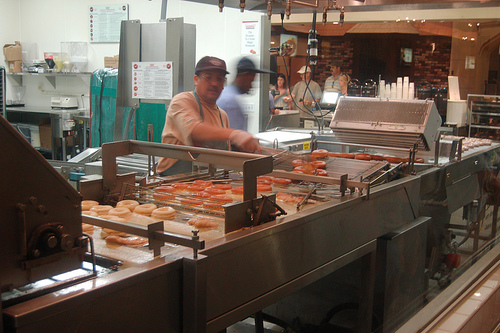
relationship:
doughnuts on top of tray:
[310, 146, 325, 157] [271, 147, 382, 186]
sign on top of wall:
[87, 7, 127, 43] [4, 2, 256, 128]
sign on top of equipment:
[132, 59, 173, 99] [122, 19, 196, 102]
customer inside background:
[270, 61, 351, 112] [272, 19, 500, 116]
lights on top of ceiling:
[349, 2, 371, 7] [284, 0, 499, 24]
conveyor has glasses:
[156, 56, 262, 177] [200, 75, 228, 88]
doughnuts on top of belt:
[310, 146, 325, 157] [271, 147, 382, 186]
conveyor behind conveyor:
[156, 56, 262, 177] [15, 92, 499, 308]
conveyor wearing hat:
[156, 56, 262, 177] [196, 56, 229, 72]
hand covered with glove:
[228, 130, 258, 156] [233, 127, 261, 151]